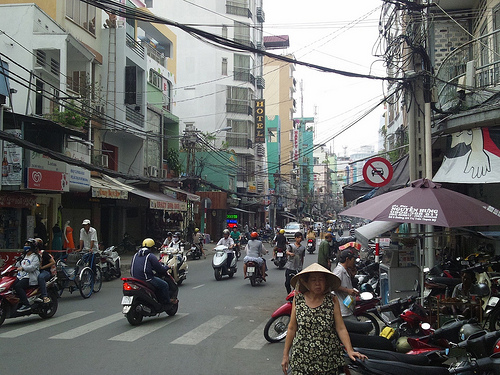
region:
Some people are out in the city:
[16, 33, 482, 358]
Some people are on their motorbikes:
[5, 17, 491, 368]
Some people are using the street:
[5, 11, 491, 357]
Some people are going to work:
[20, 48, 443, 373]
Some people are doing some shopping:
[10, 23, 491, 368]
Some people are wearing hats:
[20, 23, 490, 373]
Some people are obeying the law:
[5, 28, 470, 358]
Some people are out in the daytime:
[28, 53, 493, 368]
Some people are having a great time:
[25, 43, 475, 373]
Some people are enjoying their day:
[32, 50, 463, 373]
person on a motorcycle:
[135, 235, 173, 321]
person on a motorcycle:
[0, 242, 35, 307]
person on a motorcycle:
[169, 237, 186, 273]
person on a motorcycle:
[210, 232, 238, 278]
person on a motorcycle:
[252, 237, 270, 286]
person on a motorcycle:
[270, 228, 285, 266]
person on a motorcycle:
[304, 224, 314, 248]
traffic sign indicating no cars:
[361, 156, 394, 188]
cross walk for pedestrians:
[43, 303, 250, 351]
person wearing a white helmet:
[221, 226, 233, 244]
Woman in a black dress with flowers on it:
[278, 257, 364, 372]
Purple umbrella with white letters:
[336, 178, 498, 231]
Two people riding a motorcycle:
[5, 234, 59, 321]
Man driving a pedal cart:
[56, 217, 106, 299]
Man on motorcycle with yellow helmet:
[121, 237, 183, 322]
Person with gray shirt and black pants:
[281, 229, 308, 295]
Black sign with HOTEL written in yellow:
[250, 95, 267, 145]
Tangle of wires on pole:
[371, 4, 446, 187]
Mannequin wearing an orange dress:
[60, 217, 77, 249]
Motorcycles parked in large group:
[261, 239, 498, 371]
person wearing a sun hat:
[285, 260, 343, 303]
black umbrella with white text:
[355, 170, 490, 225]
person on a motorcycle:
[245, 240, 263, 282]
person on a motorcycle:
[303, 228, 310, 248]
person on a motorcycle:
[185, 234, 208, 259]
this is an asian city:
[57, 153, 196, 358]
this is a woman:
[240, 302, 309, 359]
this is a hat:
[288, 196, 366, 293]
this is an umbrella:
[359, 166, 437, 211]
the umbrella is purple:
[364, 121, 496, 245]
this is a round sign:
[341, 148, 398, 179]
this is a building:
[196, 70, 262, 169]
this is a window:
[209, 88, 261, 179]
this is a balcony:
[241, 134, 255, 158]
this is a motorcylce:
[71, 222, 205, 373]